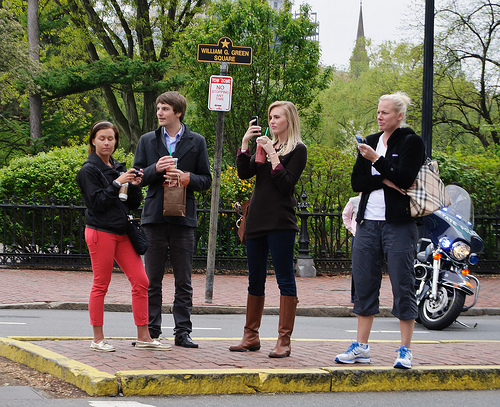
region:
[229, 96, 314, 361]
woman wearing a boot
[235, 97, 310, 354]
women holding a cellphone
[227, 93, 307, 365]
woman wearing a blue skinny jean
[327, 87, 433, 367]
woman wearing a runner shoe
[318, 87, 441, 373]
woman is wearing a black jacket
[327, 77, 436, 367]
woman is holding a cell phone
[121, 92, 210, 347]
a man is holding a beverage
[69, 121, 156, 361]
woman wearing a red jean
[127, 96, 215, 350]
man wearing a coat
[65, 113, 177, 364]
woman using her cellphone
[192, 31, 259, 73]
William G. Green Square on a sign.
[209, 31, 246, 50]
Star on the sign.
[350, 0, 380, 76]
Pointed building in the background.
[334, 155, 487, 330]
Motorcycle behind the people.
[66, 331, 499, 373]
The meridian is brick.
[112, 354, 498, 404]
Side of the meridian is yellow.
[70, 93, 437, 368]
Four people in the meridian.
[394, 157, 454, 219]
Woman is carrying a purse.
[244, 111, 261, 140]
Girl is taking a picture.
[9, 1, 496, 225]
Trees in the background.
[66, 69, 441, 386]
people standing on a median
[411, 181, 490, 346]
motorcycle on the street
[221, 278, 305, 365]
boots on a woman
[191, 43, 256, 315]
sign on a pole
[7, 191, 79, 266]
black fence by the sidewalk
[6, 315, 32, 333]
white line painted on the street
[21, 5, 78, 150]
trunk of a tree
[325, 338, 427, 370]
sneakers on a woman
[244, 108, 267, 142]
phone in woman's hand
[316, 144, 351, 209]
green bush behind fence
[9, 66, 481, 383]
people standing on side walk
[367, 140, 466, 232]
woman holding burberry hand bag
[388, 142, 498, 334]
blue motorcycle parked on road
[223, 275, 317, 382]
lady wearing brown boots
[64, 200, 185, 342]
woman wearing red jeans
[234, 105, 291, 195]
lady holding cell phone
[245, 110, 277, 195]
lady holding smoothie cup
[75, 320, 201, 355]
lady wearing gold shoes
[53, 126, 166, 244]
lady wearing black jacket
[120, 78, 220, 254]
man wearing black jacket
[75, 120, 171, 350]
a pedestrian standing in median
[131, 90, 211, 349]
a pedestrian standing in median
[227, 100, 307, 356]
a pedestrian standing in median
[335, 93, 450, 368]
a pedestrian standing in median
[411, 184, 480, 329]
a parked police motorcycle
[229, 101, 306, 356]
a woman taking photograph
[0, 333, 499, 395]
a red brick median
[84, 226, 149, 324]
a pair of red pants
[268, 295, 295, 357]
a woman's brown leather boot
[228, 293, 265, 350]
a woman's brown leather boot